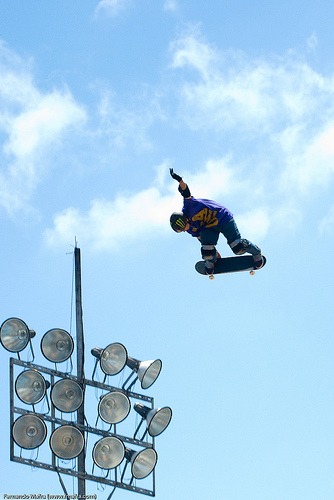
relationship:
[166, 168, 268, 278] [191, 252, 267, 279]
skateboarder performing trick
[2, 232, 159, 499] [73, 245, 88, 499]
wires connecting to pole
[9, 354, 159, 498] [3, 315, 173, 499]
metal support lights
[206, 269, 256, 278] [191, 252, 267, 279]
wheels on skateboard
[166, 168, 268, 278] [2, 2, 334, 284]
skateboarder against clouds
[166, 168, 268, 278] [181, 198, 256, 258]
skateboarder wearing outift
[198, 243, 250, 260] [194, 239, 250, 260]
knee pads covering joints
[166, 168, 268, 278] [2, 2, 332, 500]
skater in air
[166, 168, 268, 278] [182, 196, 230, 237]
skater wearing blue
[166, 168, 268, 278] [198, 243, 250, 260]
skater wearing knee pads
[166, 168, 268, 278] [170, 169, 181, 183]
skater wearing gloves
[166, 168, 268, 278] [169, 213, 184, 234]
skater wearing helmet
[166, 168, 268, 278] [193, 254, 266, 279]
skater holding skateboard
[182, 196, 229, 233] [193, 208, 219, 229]
shirt has yellow writing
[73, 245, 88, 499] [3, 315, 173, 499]
pole has many lights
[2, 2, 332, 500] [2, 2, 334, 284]
sky with clouds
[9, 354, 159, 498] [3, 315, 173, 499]
pannel of lights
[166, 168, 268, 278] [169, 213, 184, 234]
skateboarder wearing helmet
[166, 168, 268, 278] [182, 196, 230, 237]
skateboarder wearing blue and yellow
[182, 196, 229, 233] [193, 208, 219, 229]
shirt with yellow design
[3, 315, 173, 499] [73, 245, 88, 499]
lights on pole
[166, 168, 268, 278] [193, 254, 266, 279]
guy on skateboard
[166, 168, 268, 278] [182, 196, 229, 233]
guy wearing shirt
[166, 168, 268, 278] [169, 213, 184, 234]
guy wearing helmet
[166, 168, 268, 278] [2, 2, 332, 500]
man in sky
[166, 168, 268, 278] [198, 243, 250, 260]
skateboarder wearing knee pads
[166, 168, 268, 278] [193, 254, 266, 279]
skater on skateboard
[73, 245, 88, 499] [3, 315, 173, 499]
pole holds lights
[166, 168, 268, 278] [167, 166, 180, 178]
skater has glove